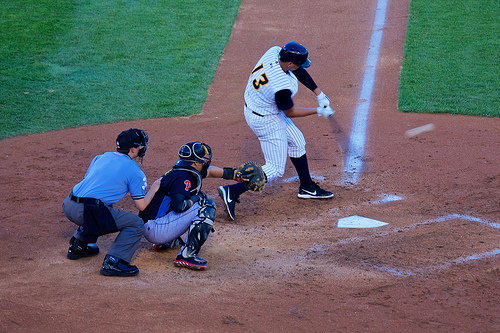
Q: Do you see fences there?
A: No, there are no fences.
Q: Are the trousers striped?
A: Yes, the trousers are striped.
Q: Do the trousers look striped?
A: Yes, the trousers are striped.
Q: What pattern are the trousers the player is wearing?
A: The pants are striped.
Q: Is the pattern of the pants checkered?
A: No, the pants are striped.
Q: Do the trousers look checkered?
A: No, the trousers are striped.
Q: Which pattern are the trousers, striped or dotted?
A: The trousers are striped.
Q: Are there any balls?
A: Yes, there is a ball.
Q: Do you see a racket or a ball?
A: Yes, there is a ball.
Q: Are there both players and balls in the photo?
A: Yes, there are both a ball and a player.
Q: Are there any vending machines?
A: No, there are no vending machines.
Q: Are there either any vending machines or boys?
A: No, there are no vending machines or boys.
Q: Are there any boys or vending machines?
A: No, there are no vending machines or boys.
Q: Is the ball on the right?
A: Yes, the ball is on the right of the image.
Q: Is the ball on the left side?
A: No, the ball is on the right of the image.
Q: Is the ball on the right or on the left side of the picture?
A: The ball is on the right of the image.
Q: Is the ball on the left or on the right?
A: The ball is on the right of the image.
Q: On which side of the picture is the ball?
A: The ball is on the right of the image.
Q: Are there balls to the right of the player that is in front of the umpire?
A: Yes, there is a ball to the right of the player.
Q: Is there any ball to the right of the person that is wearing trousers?
A: Yes, there is a ball to the right of the player.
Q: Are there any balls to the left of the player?
A: No, the ball is to the right of the player.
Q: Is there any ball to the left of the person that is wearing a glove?
A: No, the ball is to the right of the player.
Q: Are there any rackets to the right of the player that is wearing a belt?
A: No, there is a ball to the right of the player.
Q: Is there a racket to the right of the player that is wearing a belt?
A: No, there is a ball to the right of the player.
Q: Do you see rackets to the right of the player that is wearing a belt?
A: No, there is a ball to the right of the player.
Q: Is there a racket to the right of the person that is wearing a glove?
A: No, there is a ball to the right of the player.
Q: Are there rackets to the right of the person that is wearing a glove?
A: No, there is a ball to the right of the player.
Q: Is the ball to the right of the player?
A: Yes, the ball is to the right of the player.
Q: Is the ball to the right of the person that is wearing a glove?
A: Yes, the ball is to the right of the player.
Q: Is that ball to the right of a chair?
A: No, the ball is to the right of the player.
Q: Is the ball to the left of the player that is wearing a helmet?
A: No, the ball is to the right of the player.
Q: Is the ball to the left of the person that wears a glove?
A: No, the ball is to the right of the player.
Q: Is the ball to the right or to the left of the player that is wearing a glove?
A: The ball is to the right of the player.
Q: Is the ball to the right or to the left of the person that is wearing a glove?
A: The ball is to the right of the player.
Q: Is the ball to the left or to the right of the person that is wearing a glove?
A: The ball is to the right of the player.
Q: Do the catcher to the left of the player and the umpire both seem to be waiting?
A: Yes, both the catcher and the umpire are waiting.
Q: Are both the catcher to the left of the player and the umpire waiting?
A: Yes, both the catcher and the umpire are waiting.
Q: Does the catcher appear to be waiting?
A: Yes, the catcher is waiting.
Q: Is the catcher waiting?
A: Yes, the catcher is waiting.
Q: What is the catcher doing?
A: The catcher is waiting.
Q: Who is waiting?
A: The catcher is waiting.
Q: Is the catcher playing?
A: No, the catcher is waiting.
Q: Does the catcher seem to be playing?
A: No, the catcher is waiting.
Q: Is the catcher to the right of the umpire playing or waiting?
A: The catcher is waiting.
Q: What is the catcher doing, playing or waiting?
A: The catcher is waiting.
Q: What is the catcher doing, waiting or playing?
A: The catcher is waiting.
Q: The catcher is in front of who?
A: The catcher is in front of the umpire.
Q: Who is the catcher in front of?
A: The catcher is in front of the umpire.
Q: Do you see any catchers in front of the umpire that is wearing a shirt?
A: Yes, there is a catcher in front of the umpire.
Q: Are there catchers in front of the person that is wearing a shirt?
A: Yes, there is a catcher in front of the umpire.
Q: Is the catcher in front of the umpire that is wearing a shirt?
A: Yes, the catcher is in front of the umpire.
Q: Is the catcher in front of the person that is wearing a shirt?
A: Yes, the catcher is in front of the umpire.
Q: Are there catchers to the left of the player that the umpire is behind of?
A: Yes, there is a catcher to the left of the player.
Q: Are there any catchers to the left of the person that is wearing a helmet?
A: Yes, there is a catcher to the left of the player.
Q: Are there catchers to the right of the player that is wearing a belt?
A: No, the catcher is to the left of the player.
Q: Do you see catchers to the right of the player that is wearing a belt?
A: No, the catcher is to the left of the player.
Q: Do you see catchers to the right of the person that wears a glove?
A: No, the catcher is to the left of the player.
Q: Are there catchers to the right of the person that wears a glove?
A: No, the catcher is to the left of the player.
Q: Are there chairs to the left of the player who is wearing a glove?
A: No, there is a catcher to the left of the player.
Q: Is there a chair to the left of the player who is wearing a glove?
A: No, there is a catcher to the left of the player.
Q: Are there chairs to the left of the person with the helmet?
A: No, there is a catcher to the left of the player.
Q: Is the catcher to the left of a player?
A: Yes, the catcher is to the left of a player.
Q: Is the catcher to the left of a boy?
A: No, the catcher is to the left of a player.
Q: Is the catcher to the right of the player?
A: No, the catcher is to the left of the player.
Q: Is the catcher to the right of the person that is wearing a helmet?
A: No, the catcher is to the left of the player.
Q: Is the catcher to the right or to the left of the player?
A: The catcher is to the left of the player.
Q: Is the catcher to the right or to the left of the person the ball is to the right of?
A: The catcher is to the left of the player.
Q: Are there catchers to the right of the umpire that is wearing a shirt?
A: Yes, there is a catcher to the right of the umpire.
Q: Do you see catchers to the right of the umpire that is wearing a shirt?
A: Yes, there is a catcher to the right of the umpire.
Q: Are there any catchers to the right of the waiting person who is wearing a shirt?
A: Yes, there is a catcher to the right of the umpire.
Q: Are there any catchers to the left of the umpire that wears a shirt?
A: No, the catcher is to the right of the umpire.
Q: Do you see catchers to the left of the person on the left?
A: No, the catcher is to the right of the umpire.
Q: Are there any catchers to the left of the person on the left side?
A: No, the catcher is to the right of the umpire.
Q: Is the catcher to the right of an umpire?
A: Yes, the catcher is to the right of an umpire.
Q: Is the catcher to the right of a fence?
A: No, the catcher is to the right of an umpire.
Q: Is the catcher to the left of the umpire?
A: No, the catcher is to the right of the umpire.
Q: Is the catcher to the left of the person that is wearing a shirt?
A: No, the catcher is to the right of the umpire.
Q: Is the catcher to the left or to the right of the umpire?
A: The catcher is to the right of the umpire.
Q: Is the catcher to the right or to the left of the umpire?
A: The catcher is to the right of the umpire.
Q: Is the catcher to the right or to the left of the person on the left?
A: The catcher is to the right of the umpire.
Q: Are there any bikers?
A: No, there are no bikers.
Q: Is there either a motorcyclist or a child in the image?
A: No, there are no bikers or children.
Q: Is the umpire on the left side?
A: Yes, the umpire is on the left of the image.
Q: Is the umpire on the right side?
A: No, the umpire is on the left of the image.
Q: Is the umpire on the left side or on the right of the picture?
A: The umpire is on the left of the image.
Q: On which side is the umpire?
A: The umpire is on the left of the image.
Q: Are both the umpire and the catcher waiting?
A: Yes, both the umpire and the catcher are waiting.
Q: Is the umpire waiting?
A: Yes, the umpire is waiting.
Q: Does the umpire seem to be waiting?
A: Yes, the umpire is waiting.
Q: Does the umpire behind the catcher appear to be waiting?
A: Yes, the umpire is waiting.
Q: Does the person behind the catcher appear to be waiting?
A: Yes, the umpire is waiting.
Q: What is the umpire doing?
A: The umpire is waiting.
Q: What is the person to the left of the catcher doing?
A: The umpire is waiting.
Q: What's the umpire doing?
A: The umpire is waiting.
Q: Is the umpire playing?
A: No, the umpire is waiting.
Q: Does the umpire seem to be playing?
A: No, the umpire is waiting.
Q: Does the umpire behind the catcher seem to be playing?
A: No, the umpire is waiting.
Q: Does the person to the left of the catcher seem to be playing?
A: No, the umpire is waiting.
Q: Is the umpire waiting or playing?
A: The umpire is waiting.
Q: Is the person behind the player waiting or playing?
A: The umpire is waiting.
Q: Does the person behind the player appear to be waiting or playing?
A: The umpire is waiting.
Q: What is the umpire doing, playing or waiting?
A: The umpire is waiting.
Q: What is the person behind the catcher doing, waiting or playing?
A: The umpire is waiting.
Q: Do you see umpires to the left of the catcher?
A: Yes, there is an umpire to the left of the catcher.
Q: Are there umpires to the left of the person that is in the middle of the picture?
A: Yes, there is an umpire to the left of the catcher.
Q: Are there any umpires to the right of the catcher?
A: No, the umpire is to the left of the catcher.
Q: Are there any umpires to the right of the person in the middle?
A: No, the umpire is to the left of the catcher.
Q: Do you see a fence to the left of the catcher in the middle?
A: No, there is an umpire to the left of the catcher.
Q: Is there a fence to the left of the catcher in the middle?
A: No, there is an umpire to the left of the catcher.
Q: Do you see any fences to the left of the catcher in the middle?
A: No, there is an umpire to the left of the catcher.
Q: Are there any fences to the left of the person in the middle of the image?
A: No, there is an umpire to the left of the catcher.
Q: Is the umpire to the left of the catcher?
A: Yes, the umpire is to the left of the catcher.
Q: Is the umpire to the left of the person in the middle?
A: Yes, the umpire is to the left of the catcher.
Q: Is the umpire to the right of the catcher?
A: No, the umpire is to the left of the catcher.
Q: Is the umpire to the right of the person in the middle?
A: No, the umpire is to the left of the catcher.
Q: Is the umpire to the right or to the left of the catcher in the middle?
A: The umpire is to the left of the catcher.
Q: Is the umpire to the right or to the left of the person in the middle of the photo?
A: The umpire is to the left of the catcher.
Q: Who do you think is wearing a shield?
A: The umpire is wearing a shield.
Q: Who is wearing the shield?
A: The umpire is wearing a shield.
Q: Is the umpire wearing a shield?
A: Yes, the umpire is wearing a shield.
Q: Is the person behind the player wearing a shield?
A: Yes, the umpire is wearing a shield.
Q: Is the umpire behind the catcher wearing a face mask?
A: No, the umpire is wearing a shield.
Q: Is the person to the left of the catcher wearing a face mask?
A: No, the umpire is wearing a shield.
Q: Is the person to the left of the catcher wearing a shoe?
A: Yes, the umpire is wearing a shoe.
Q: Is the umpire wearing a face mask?
A: No, the umpire is wearing a shoe.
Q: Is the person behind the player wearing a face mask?
A: No, the umpire is wearing a shoe.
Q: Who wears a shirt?
A: The umpire wears a shirt.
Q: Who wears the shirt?
A: The umpire wears a shirt.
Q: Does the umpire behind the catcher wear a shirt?
A: Yes, the umpire wears a shirt.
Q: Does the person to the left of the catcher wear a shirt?
A: Yes, the umpire wears a shirt.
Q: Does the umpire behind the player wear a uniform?
A: No, the umpire wears a shirt.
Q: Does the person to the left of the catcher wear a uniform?
A: No, the umpire wears a shirt.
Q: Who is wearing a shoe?
A: The umpire is wearing a shoe.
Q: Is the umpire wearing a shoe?
A: Yes, the umpire is wearing a shoe.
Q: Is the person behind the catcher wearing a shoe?
A: Yes, the umpire is wearing a shoe.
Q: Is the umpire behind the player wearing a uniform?
A: No, the umpire is wearing a shoe.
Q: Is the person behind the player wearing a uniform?
A: No, the umpire is wearing a shoe.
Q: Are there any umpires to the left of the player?
A: Yes, there is an umpire to the left of the player.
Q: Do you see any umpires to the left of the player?
A: Yes, there is an umpire to the left of the player.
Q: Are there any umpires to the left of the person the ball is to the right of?
A: Yes, there is an umpire to the left of the player.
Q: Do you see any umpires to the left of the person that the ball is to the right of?
A: Yes, there is an umpire to the left of the player.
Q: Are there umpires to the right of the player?
A: No, the umpire is to the left of the player.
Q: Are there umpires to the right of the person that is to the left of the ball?
A: No, the umpire is to the left of the player.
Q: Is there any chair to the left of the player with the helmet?
A: No, there is an umpire to the left of the player.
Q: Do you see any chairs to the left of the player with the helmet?
A: No, there is an umpire to the left of the player.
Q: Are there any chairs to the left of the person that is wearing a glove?
A: No, there is an umpire to the left of the player.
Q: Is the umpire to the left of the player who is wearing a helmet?
A: Yes, the umpire is to the left of the player.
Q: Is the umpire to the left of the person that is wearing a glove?
A: Yes, the umpire is to the left of the player.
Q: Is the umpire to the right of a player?
A: No, the umpire is to the left of a player.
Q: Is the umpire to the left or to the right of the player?
A: The umpire is to the left of the player.